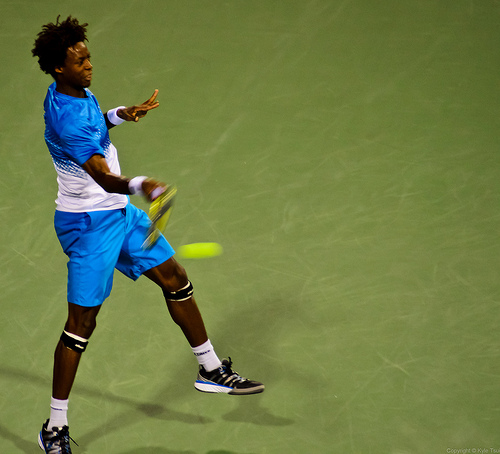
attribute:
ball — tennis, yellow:
[185, 220, 226, 258]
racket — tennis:
[141, 190, 175, 250]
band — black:
[64, 320, 90, 352]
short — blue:
[44, 208, 178, 302]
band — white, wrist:
[128, 174, 146, 194]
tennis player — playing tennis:
[34, 19, 314, 373]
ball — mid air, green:
[159, 225, 246, 263]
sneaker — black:
[178, 356, 277, 393]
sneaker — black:
[190, 372, 291, 383]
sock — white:
[174, 316, 282, 425]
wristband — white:
[87, 91, 172, 174]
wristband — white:
[100, 83, 143, 235]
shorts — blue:
[44, 183, 199, 283]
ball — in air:
[156, 224, 234, 281]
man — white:
[8, 11, 304, 359]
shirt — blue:
[25, 77, 166, 216]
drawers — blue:
[35, 185, 207, 316]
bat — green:
[119, 165, 204, 258]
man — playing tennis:
[14, 10, 294, 411]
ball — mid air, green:
[164, 222, 237, 269]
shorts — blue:
[37, 182, 235, 314]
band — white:
[124, 159, 147, 200]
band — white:
[103, 95, 132, 135]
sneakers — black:
[181, 360, 280, 411]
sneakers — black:
[24, 391, 91, 451]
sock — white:
[174, 333, 232, 374]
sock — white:
[33, 389, 79, 439]